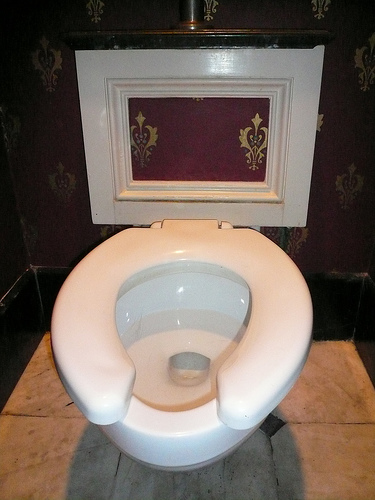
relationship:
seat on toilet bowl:
[45, 212, 321, 427] [51, 220, 313, 471]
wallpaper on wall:
[136, 102, 264, 172] [5, 7, 371, 247]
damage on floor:
[258, 408, 285, 439] [6, 430, 374, 498]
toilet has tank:
[47, 29, 338, 475] [67, 35, 326, 224]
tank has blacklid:
[67, 35, 326, 224] [67, 28, 338, 52]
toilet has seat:
[42, 225, 308, 478] [45, 212, 321, 427]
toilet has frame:
[42, 225, 308, 478] [75, 43, 317, 230]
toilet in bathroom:
[47, 29, 338, 475] [4, 1, 363, 494]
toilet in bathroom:
[29, 109, 318, 475] [4, 1, 363, 494]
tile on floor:
[293, 371, 361, 470] [7, 374, 59, 494]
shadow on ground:
[64, 409, 300, 499] [3, 322, 373, 496]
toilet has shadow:
[42, 225, 308, 478] [64, 409, 300, 499]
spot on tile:
[258, 413, 286, 436] [0, 320, 371, 496]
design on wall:
[124, 111, 163, 173] [3, 4, 363, 272]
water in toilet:
[124, 310, 247, 411] [42, 225, 308, 478]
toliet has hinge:
[50, 213, 313, 472] [150, 218, 233, 232]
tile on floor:
[299, 385, 353, 441] [19, 375, 100, 489]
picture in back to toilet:
[79, 51, 317, 236] [57, 229, 322, 466]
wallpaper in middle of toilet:
[126, 98, 267, 182] [51, 218, 322, 410]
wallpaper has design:
[1, 0, 374, 268] [128, 110, 158, 165]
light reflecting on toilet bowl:
[36, 293, 297, 460] [101, 336, 300, 479]